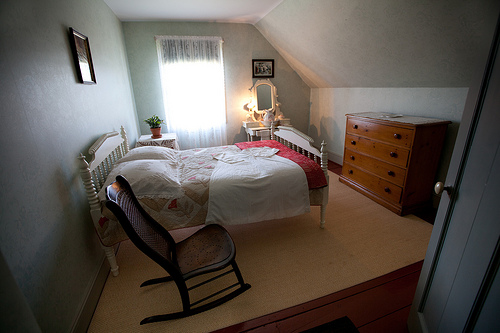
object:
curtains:
[154, 33, 228, 151]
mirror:
[249, 78, 276, 118]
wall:
[121, 19, 310, 147]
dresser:
[336, 110, 450, 217]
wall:
[306, 88, 465, 204]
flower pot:
[145, 126, 165, 138]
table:
[135, 133, 179, 150]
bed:
[75, 121, 331, 279]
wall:
[0, 0, 142, 332]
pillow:
[118, 143, 178, 159]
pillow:
[95, 158, 182, 203]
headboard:
[75, 124, 129, 280]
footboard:
[264, 117, 330, 170]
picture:
[66, 27, 97, 86]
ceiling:
[102, 0, 287, 27]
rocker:
[104, 174, 251, 326]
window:
[154, 34, 228, 152]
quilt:
[91, 139, 328, 248]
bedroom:
[0, 0, 499, 332]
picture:
[250, 58, 276, 81]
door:
[402, 22, 499, 332]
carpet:
[87, 169, 437, 333]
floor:
[78, 156, 438, 332]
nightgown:
[201, 140, 310, 230]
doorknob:
[429, 178, 451, 198]